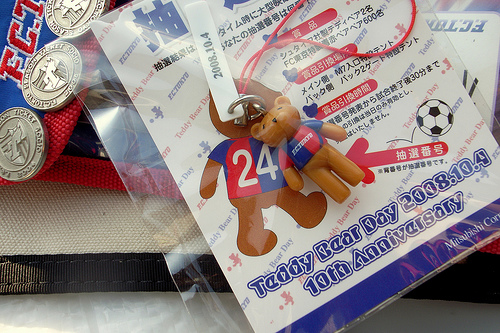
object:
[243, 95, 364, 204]
bear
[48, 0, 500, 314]
package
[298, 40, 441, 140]
writing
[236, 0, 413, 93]
string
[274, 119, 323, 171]
jersey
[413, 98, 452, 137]
soccer ball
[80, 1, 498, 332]
card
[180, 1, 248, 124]
id tag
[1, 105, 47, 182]
coin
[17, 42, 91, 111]
coin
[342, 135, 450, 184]
arrow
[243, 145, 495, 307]
writing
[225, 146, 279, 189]
number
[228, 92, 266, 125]
key chain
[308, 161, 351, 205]
legs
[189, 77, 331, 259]
drawing